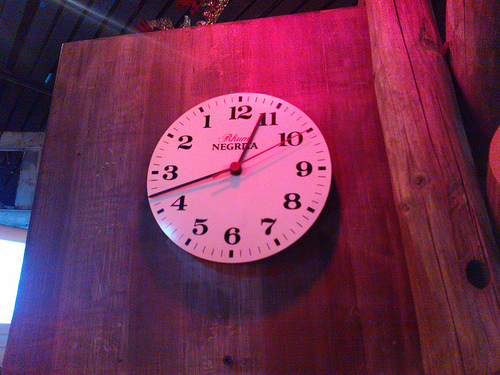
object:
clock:
[142, 87, 338, 268]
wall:
[0, 0, 500, 374]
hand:
[231, 132, 302, 167]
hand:
[145, 164, 235, 198]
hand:
[235, 113, 266, 167]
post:
[363, 1, 498, 367]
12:
[228, 103, 257, 121]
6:
[220, 223, 246, 249]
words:
[210, 141, 262, 153]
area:
[3, 238, 45, 309]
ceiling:
[1, 0, 364, 131]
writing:
[209, 141, 265, 152]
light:
[0, 236, 28, 329]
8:
[280, 188, 307, 213]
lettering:
[218, 131, 253, 144]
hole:
[463, 259, 494, 291]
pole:
[441, 0, 500, 180]